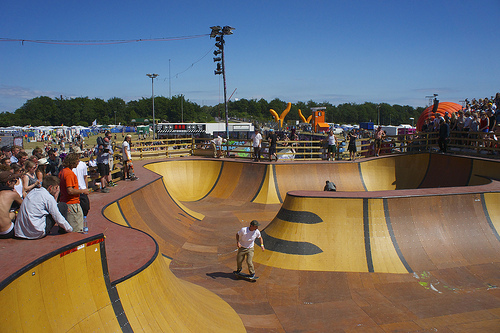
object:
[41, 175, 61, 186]
mans hair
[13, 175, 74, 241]
man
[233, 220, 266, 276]
body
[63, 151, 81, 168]
hair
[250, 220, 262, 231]
head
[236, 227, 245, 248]
arm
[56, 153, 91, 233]
man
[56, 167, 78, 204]
shirt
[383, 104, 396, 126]
tree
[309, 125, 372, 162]
crowd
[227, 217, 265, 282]
skate boarder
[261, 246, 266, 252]
hand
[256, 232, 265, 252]
arm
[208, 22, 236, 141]
lamp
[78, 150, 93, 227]
man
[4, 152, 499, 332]
ramp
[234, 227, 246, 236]
sleeve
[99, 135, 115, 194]
people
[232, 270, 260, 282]
skateboard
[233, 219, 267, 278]
man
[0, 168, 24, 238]
man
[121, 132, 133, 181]
man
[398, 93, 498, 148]
crowd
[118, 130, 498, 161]
fence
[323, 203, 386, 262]
yellow painted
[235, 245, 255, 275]
pants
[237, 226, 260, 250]
t shirt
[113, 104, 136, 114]
leaves